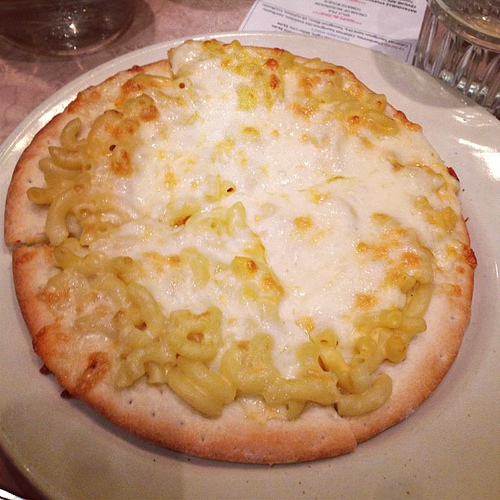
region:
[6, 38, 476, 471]
Pizza crust with macaroni and cheese toppings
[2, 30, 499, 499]
White serving plate with macaroni and cheese topped pizza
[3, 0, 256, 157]
Pink marbled tablecloth under a plate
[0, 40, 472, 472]
Fully cooked pizza cut into 4 pieces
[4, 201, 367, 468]
Single piece of pizza with macaroni and melted cheese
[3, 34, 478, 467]
Macaroni and melted cheese on top of pizza crust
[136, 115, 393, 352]
Melted cheese mixed with macaroni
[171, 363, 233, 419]
hardened yellow macaroni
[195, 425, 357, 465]
medium brown hard crust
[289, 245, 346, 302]
melted white bubbly cheese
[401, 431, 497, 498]
cream colored ceramic pizza dish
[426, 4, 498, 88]
fancy reflective water glass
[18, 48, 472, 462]
macaroni and cheese pizza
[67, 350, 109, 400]
very brown toasted piece of crust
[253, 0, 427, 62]
back of meal receipt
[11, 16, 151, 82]
shadow of glassware cast upon table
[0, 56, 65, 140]
pink granite patterned tabletop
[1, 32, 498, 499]
large white circular plate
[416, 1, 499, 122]
clear glass beside plate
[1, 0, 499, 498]
pink table top under plate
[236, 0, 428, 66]
white menu under plate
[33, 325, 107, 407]
burned pizza spot on bottom left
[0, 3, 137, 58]
reflective metal container on table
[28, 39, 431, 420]
pasta on pizza is elbow macaroni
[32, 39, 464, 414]
orange and yellow cheese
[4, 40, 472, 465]
pizza is cut into four slices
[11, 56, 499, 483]
this is a pizza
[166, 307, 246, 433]
macron toppings on a pizza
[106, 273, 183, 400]
macron toppings on a pizza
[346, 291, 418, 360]
macron toppings on a pizza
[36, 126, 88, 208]
macron toppings on a pizza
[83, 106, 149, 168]
macron toppings on a pizza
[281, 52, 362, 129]
macron toppings on a pizza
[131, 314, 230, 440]
macron toppings on a pizza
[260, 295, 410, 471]
a section of a pizza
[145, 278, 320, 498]
a section of a pizza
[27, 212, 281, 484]
a section of a pizza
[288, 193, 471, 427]
a section of a pizza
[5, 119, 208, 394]
a section of a pizza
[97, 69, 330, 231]
a section of a pizza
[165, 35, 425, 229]
a section of a pizza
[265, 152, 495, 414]
a section of a pizza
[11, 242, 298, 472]
a section of a pizza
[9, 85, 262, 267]
a section of a pizza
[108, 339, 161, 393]
Small macroni on a pizza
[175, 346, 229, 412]
Small macroni on a pizza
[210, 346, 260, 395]
Small macroni on a pizza